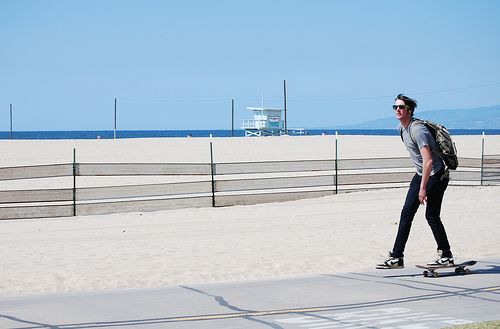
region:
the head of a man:
[388, 89, 418, 128]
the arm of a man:
[408, 125, 438, 187]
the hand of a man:
[411, 183, 431, 203]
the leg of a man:
[388, 174, 425, 256]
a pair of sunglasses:
[390, 101, 413, 112]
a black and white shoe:
[369, 250, 411, 276]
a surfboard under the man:
[414, 254, 483, 285]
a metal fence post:
[328, 126, 345, 200]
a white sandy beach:
[0, 133, 499, 296]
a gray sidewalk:
[0, 254, 498, 326]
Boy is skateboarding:
[361, 71, 483, 281]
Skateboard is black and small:
[410, 255, 480, 282]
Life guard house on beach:
[239, 87, 301, 135]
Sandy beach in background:
[11, 135, 492, 255]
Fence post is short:
[192, 131, 227, 207]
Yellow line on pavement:
[176, 302, 365, 312]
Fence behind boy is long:
[13, 147, 403, 226]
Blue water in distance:
[7, 129, 402, 139]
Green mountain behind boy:
[427, 108, 498, 128]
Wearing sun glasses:
[393, 89, 423, 114]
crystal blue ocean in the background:
[132, 122, 238, 148]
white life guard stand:
[230, 97, 295, 141]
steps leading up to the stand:
[264, 119, 318, 140]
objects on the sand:
[304, 119, 341, 141]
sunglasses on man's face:
[375, 100, 417, 116]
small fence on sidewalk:
[25, 150, 338, 220]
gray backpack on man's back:
[417, 106, 480, 182]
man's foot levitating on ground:
[362, 242, 427, 289]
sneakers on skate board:
[393, 254, 481, 283]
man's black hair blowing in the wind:
[369, 69, 421, 123]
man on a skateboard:
[376, 85, 463, 279]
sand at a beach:
[1, 134, 498, 279]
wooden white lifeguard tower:
[236, 101, 306, 142]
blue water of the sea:
[2, 126, 499, 143]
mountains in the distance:
[343, 92, 498, 144]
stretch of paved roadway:
[2, 252, 498, 327]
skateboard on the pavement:
[416, 252, 478, 278]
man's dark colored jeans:
[388, 164, 458, 259]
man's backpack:
[416, 114, 463, 173]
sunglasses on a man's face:
[391, 102, 412, 110]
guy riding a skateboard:
[377, 71, 497, 281]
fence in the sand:
[29, 145, 306, 241]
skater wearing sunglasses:
[387, 91, 431, 134]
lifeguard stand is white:
[234, 56, 342, 154]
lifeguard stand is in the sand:
[241, 97, 318, 178]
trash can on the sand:
[179, 123, 202, 144]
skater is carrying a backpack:
[389, 126, 481, 175]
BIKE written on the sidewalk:
[277, 297, 456, 327]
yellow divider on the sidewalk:
[169, 295, 353, 321]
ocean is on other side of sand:
[71, 117, 228, 144]